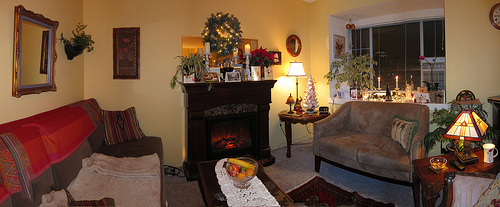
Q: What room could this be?
A: It is a living room.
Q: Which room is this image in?
A: It is at the living room.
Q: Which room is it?
A: It is a living room.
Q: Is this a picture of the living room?
A: Yes, it is showing the living room.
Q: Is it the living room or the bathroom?
A: It is the living room.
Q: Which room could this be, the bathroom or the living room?
A: It is the living room.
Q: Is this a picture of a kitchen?
A: No, the picture is showing a living room.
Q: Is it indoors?
A: Yes, it is indoors.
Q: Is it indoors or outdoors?
A: It is indoors.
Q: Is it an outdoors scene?
A: No, it is indoors.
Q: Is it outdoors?
A: No, it is indoors.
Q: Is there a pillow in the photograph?
A: Yes, there is a pillow.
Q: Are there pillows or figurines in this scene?
A: Yes, there is a pillow.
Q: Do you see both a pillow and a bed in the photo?
A: No, there is a pillow but no beds.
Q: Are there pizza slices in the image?
A: No, there are no pizza slices.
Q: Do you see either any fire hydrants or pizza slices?
A: No, there are no pizza slices or fire hydrants.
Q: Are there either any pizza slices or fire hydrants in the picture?
A: No, there are no pizza slices or fire hydrants.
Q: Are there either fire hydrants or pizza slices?
A: No, there are no pizza slices or fire hydrants.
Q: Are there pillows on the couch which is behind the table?
A: Yes, there is a pillow on the couch.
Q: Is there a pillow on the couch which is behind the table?
A: Yes, there is a pillow on the couch.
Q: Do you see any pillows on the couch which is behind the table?
A: Yes, there is a pillow on the couch.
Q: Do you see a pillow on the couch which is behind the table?
A: Yes, there is a pillow on the couch.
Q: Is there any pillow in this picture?
A: Yes, there is a pillow.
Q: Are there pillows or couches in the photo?
A: Yes, there is a pillow.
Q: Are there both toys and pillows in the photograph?
A: No, there is a pillow but no toys.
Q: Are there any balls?
A: No, there are no balls.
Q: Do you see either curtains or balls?
A: No, there are no balls or curtains.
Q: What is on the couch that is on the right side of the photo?
A: The pillow is on the couch.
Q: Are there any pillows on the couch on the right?
A: Yes, there is a pillow on the couch.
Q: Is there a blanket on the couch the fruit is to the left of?
A: No, there is a pillow on the couch.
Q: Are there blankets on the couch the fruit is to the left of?
A: No, there is a pillow on the couch.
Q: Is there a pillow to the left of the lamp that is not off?
A: Yes, there is a pillow to the left of the lamp.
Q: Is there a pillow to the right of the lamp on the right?
A: No, the pillow is to the left of the lamp.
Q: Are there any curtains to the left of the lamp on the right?
A: No, there is a pillow to the left of the lamp.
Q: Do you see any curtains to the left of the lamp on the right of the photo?
A: No, there is a pillow to the left of the lamp.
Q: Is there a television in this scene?
A: No, there are no televisions.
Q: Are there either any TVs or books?
A: No, there are no TVs or books.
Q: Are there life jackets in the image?
A: No, there are no life jackets.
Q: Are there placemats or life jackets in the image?
A: No, there are no life jackets or placemats.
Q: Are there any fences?
A: No, there are no fences.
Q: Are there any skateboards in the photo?
A: No, there are no skateboards.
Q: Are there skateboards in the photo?
A: No, there are no skateboards.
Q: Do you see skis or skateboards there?
A: No, there are no skateboards or skis.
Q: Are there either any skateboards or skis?
A: No, there are no skateboards or skis.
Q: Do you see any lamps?
A: Yes, there is a lamp.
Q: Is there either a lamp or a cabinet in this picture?
A: Yes, there is a lamp.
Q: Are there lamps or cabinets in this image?
A: Yes, there is a lamp.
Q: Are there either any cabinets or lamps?
A: Yes, there is a lamp.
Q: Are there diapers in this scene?
A: No, there are no diapers.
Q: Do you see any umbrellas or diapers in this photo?
A: No, there are no diapers or umbrellas.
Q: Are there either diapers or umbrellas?
A: No, there are no diapers or umbrellas.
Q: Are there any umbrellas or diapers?
A: No, there are no diapers or umbrellas.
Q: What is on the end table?
A: The lamp is on the end table.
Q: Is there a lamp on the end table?
A: Yes, there is a lamp on the end table.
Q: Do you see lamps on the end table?
A: Yes, there is a lamp on the end table.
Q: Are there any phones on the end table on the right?
A: No, there is a lamp on the end table.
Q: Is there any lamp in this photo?
A: Yes, there is a lamp.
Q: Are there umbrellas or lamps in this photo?
A: Yes, there is a lamp.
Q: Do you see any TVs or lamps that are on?
A: Yes, the lamp is on.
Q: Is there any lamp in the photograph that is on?
A: Yes, there is a lamp that is on.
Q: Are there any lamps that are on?
A: Yes, there is a lamp that is on.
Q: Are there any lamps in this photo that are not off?
A: Yes, there is a lamp that is on.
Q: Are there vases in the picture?
A: No, there are no vases.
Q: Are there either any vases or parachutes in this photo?
A: No, there are no vases or parachutes.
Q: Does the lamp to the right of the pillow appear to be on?
A: Yes, the lamp is on.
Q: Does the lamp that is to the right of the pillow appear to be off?
A: No, the lamp is on.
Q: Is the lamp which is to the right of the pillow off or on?
A: The lamp is on.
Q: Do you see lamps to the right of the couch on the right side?
A: Yes, there is a lamp to the right of the couch.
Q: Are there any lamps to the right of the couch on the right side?
A: Yes, there is a lamp to the right of the couch.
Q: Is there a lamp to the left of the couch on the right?
A: No, the lamp is to the right of the couch.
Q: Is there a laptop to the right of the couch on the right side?
A: No, there is a lamp to the right of the couch.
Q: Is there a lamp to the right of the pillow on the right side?
A: Yes, there is a lamp to the right of the pillow.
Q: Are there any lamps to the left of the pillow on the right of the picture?
A: No, the lamp is to the right of the pillow.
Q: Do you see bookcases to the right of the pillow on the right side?
A: No, there is a lamp to the right of the pillow.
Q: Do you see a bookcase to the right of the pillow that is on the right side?
A: No, there is a lamp to the right of the pillow.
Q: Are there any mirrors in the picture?
A: Yes, there is a mirror.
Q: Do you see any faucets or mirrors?
A: Yes, there is a mirror.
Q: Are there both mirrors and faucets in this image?
A: No, there is a mirror but no faucets.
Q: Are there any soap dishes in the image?
A: No, there are no soap dishes.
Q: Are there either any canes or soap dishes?
A: No, there are no soap dishes or canes.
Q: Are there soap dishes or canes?
A: No, there are no soap dishes or canes.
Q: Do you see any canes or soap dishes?
A: No, there are no soap dishes or canes.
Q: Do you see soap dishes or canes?
A: No, there are no soap dishes or canes.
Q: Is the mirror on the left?
A: Yes, the mirror is on the left of the image.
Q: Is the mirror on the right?
A: No, the mirror is on the left of the image.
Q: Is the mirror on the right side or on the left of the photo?
A: The mirror is on the left of the image.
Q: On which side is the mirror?
A: The mirror is on the left of the image.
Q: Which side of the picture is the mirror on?
A: The mirror is on the left of the image.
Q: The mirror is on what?
A: The mirror is on the wall.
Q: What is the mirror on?
A: The mirror is on the wall.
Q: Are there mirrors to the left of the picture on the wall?
A: Yes, there is a mirror to the left of the picture.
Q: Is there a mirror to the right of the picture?
A: No, the mirror is to the left of the picture.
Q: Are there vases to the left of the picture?
A: No, there is a mirror to the left of the picture.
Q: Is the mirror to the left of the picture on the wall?
A: Yes, the mirror is to the left of the picture.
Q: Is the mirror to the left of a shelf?
A: No, the mirror is to the left of the picture.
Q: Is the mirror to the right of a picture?
A: No, the mirror is to the left of a picture.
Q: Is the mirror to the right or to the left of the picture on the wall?
A: The mirror is to the left of the picture.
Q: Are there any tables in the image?
A: Yes, there is a table.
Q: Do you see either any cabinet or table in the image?
A: Yes, there is a table.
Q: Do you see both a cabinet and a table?
A: No, there is a table but no cabinets.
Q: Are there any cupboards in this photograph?
A: No, there are no cupboards.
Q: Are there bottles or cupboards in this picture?
A: No, there are no cupboards or bottles.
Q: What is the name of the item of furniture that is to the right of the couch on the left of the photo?
A: The piece of furniture is a table.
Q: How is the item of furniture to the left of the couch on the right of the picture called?
A: The piece of furniture is a table.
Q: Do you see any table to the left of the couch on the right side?
A: Yes, there is a table to the left of the couch.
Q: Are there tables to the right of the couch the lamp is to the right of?
A: No, the table is to the left of the couch.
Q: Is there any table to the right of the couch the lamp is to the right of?
A: No, the table is to the left of the couch.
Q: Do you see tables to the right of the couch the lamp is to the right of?
A: No, the table is to the left of the couch.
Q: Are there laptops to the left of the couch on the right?
A: No, there is a table to the left of the couch.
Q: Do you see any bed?
A: No, there are no beds.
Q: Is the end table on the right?
A: Yes, the end table is on the right of the image.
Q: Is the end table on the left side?
A: No, the end table is on the right of the image.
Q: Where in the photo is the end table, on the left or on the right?
A: The end table is on the right of the image.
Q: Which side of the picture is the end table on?
A: The end table is on the right of the image.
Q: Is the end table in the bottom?
A: Yes, the end table is in the bottom of the image.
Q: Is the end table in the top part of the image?
A: No, the end table is in the bottom of the image.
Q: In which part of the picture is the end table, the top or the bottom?
A: The end table is in the bottom of the image.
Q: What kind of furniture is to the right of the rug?
A: The piece of furniture is an end table.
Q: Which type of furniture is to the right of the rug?
A: The piece of furniture is an end table.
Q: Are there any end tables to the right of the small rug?
A: Yes, there is an end table to the right of the rug.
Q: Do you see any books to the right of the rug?
A: No, there is an end table to the right of the rug.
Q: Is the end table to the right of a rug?
A: Yes, the end table is to the right of a rug.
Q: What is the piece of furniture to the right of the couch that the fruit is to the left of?
A: The piece of furniture is an end table.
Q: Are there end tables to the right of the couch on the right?
A: Yes, there is an end table to the right of the couch.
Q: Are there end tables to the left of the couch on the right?
A: No, the end table is to the right of the couch.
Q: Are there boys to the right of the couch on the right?
A: No, there is an end table to the right of the couch.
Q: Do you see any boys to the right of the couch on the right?
A: No, there is an end table to the right of the couch.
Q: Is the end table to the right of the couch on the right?
A: Yes, the end table is to the right of the couch.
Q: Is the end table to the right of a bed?
A: No, the end table is to the right of the couch.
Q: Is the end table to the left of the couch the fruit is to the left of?
A: No, the end table is to the right of the couch.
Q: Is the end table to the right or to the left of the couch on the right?
A: The end table is to the right of the couch.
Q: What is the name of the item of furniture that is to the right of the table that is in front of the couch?
A: The piece of furniture is an end table.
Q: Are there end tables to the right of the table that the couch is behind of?
A: Yes, there is an end table to the right of the table.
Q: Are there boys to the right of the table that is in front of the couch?
A: No, there is an end table to the right of the table.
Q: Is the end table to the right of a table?
A: Yes, the end table is to the right of a table.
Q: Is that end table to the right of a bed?
A: No, the end table is to the right of a table.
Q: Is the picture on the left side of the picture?
A: Yes, the picture is on the left of the image.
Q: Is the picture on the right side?
A: No, the picture is on the left of the image.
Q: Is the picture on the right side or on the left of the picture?
A: The picture is on the left of the image.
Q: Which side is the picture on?
A: The picture is on the left of the image.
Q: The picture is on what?
A: The picture is on the wall.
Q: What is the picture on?
A: The picture is on the wall.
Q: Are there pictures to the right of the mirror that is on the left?
A: Yes, there is a picture to the right of the mirror.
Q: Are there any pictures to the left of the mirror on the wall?
A: No, the picture is to the right of the mirror.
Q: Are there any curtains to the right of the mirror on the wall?
A: No, there is a picture to the right of the mirror.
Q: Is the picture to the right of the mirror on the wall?
A: Yes, the picture is to the right of the mirror.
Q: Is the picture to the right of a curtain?
A: No, the picture is to the right of the mirror.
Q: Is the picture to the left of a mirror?
A: No, the picture is to the right of a mirror.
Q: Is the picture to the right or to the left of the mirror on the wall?
A: The picture is to the right of the mirror.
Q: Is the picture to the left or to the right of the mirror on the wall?
A: The picture is to the right of the mirror.